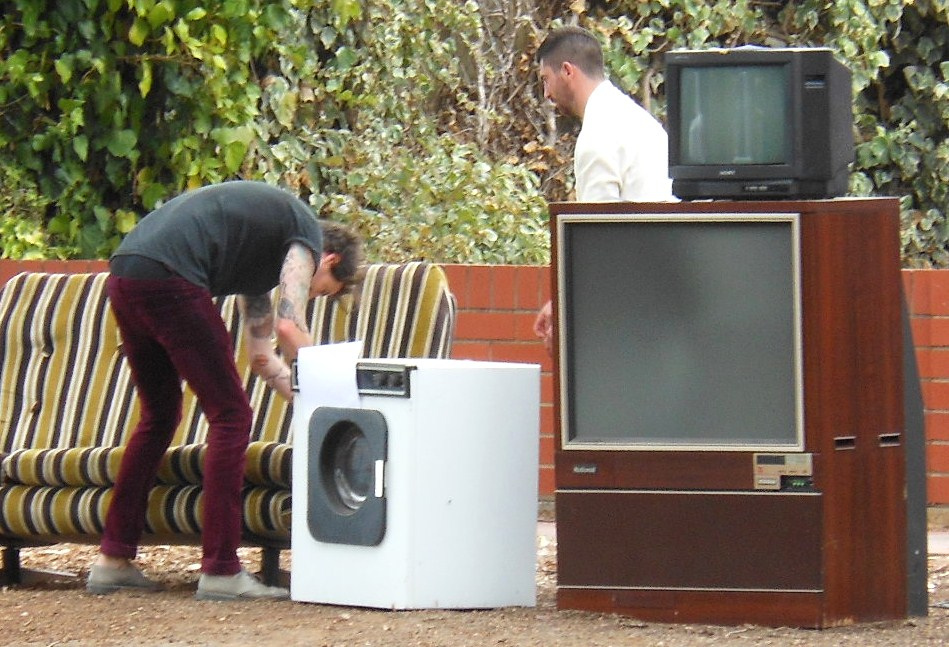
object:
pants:
[99, 275, 251, 576]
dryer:
[289, 341, 540, 611]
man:
[529, 24, 682, 339]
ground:
[220, 610, 457, 646]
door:
[310, 406, 387, 546]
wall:
[437, 265, 557, 519]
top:
[548, 201, 898, 215]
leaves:
[0, 0, 226, 254]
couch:
[0, 262, 457, 587]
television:
[666, 48, 856, 202]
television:
[546, 201, 910, 625]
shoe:
[196, 570, 291, 602]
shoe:
[86, 564, 171, 595]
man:
[80, 180, 363, 601]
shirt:
[572, 79, 682, 204]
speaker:
[556, 488, 826, 594]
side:
[802, 197, 907, 627]